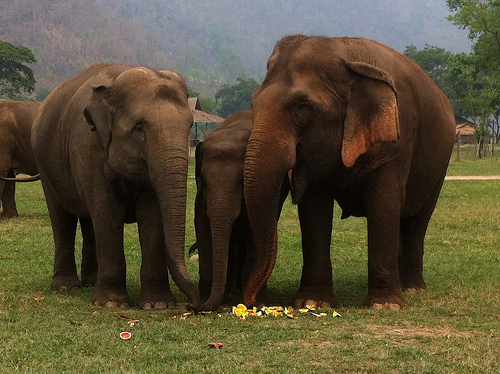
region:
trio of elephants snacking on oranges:
[33, 18, 443, 347]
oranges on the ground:
[224, 298, 332, 335]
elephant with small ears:
[28, 46, 203, 325]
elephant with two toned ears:
[230, 21, 452, 318]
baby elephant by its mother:
[185, 97, 256, 321]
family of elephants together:
[27, 28, 476, 323]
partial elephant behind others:
[3, 88, 36, 209]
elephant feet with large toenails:
[85, 273, 195, 334]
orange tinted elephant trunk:
[237, 116, 282, 336]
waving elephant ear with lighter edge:
[328, 40, 405, 170]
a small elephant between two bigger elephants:
[190, 85, 294, 327]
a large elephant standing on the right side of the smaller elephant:
[246, 23, 471, 325]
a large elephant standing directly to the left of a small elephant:
[35, 37, 196, 314]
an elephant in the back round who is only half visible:
[1, 56, 74, 254]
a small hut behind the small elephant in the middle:
[178, 73, 227, 153]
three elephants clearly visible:
[22, 26, 464, 346]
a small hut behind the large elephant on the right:
[423, 85, 490, 163]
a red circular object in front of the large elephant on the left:
[96, 315, 146, 348]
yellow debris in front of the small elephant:
[217, 297, 323, 330]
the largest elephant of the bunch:
[225, 25, 472, 325]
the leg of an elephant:
[365, 178, 404, 321]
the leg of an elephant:
[295, 194, 340, 316]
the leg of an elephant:
[400, 187, 435, 297]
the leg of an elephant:
[190, 220, 225, 299]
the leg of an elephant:
[245, 236, 272, 313]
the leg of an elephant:
[133, 197, 176, 310]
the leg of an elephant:
[92, 200, 132, 307]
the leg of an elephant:
[50, 195, 83, 287]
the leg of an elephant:
[74, 213, 113, 286]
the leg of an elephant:
[2, 174, 21, 221]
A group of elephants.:
[11, 29, 467, 307]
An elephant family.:
[62, 53, 443, 291]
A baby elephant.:
[186, 96, 279, 301]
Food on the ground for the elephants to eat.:
[92, 291, 364, 349]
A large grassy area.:
[3, 177, 498, 370]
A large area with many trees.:
[11, 0, 485, 80]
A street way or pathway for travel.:
[438, 167, 499, 194]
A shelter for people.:
[175, 79, 216, 151]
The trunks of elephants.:
[141, 132, 304, 311]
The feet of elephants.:
[27, 261, 484, 324]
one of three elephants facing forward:
[34, 51, 199, 313]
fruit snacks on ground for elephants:
[232, 302, 297, 321]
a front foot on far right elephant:
[359, 287, 409, 314]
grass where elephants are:
[18, 247, 45, 282]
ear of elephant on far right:
[337, 55, 399, 170]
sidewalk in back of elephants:
[454, 170, 498, 185]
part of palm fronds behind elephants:
[2, 30, 39, 95]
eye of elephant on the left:
[125, 120, 152, 137]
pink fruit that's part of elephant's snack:
[117, 328, 137, 342]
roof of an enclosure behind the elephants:
[191, 91, 220, 125]